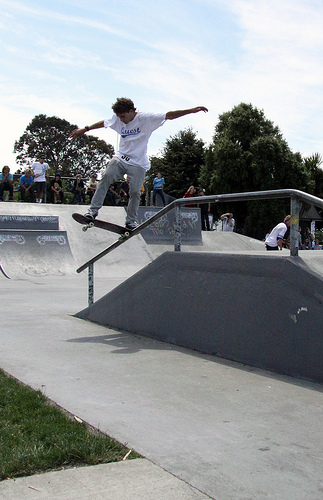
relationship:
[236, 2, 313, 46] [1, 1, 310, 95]
clouds floating in sky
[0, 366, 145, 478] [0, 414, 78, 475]
grass growing in ground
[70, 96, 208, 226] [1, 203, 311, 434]
boy skating in skate park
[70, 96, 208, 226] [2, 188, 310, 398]
boy skating in skate park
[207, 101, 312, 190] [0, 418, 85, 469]
trees growing in field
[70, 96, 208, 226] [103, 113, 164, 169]
boy wearing shirt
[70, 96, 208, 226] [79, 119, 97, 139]
boy wearing black watch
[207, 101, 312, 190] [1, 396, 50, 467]
trees growing in field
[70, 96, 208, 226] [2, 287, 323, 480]
boy skating on part of a footpath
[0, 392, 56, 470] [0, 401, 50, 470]
grass growing in ground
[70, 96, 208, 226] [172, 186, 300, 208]
boy grinding on railing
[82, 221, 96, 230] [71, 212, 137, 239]
wheels spinning on skateboard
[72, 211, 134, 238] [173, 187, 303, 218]
skateboard grinding on railing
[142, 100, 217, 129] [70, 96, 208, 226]
left hand balancing boy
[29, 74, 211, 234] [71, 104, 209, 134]
skater doing a trick balancing with arms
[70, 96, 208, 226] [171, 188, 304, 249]
boy grinding on railing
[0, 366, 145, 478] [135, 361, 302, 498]
grass growing near cement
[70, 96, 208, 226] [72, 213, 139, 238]
boy riding on board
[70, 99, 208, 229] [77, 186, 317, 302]
boy grinding down railing